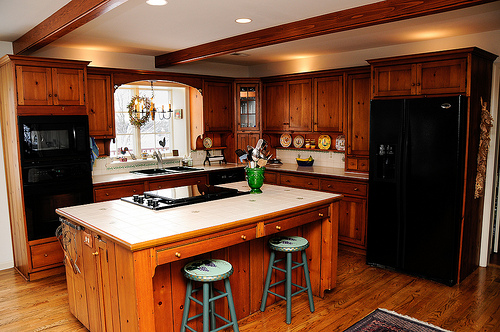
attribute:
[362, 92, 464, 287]
fridge — large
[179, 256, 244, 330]
bar stool — blue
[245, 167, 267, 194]
container — green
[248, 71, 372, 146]
cupboards — wooden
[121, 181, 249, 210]
stove top — black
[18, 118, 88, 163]
microwave — black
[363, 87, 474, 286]
fridge — black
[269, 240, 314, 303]
stool — green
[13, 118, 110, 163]
microwave — black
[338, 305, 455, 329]
rug — blue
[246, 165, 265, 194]
vase — green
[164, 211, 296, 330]
stools — green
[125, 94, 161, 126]
candle holder — small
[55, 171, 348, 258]
countertop — white